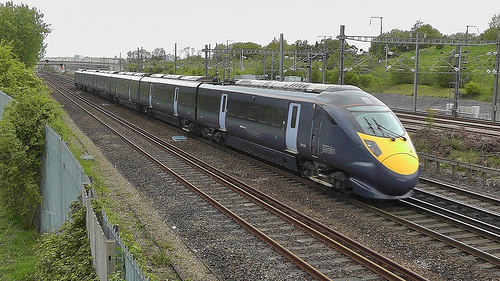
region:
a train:
[73, 30, 486, 224]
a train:
[164, 13, 422, 165]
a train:
[99, 47, 321, 192]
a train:
[178, 32, 411, 277]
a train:
[211, 68, 318, 219]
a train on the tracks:
[69, 67, 417, 207]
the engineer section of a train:
[321, 93, 421, 205]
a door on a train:
[284, 102, 303, 152]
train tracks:
[43, 78, 367, 279]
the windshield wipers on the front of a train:
[361, 116, 406, 143]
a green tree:
[1, 0, 51, 72]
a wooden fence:
[0, 90, 157, 278]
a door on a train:
[218, 90, 232, 132]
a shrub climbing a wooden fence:
[3, 78, 58, 228]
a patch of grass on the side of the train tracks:
[0, 204, 62, 278]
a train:
[220, 26, 372, 218]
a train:
[250, 87, 318, 127]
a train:
[125, 105, 320, 131]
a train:
[177, 52, 347, 145]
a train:
[236, 122, 355, 234]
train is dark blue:
[87, 56, 397, 195]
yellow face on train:
[344, 121, 415, 188]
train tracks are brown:
[97, 109, 372, 275]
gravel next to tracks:
[233, 173, 430, 256]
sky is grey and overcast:
[70, 2, 215, 53]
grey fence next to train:
[25, 118, 117, 280]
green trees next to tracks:
[16, 38, 37, 227]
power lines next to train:
[330, 22, 497, 109]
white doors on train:
[272, 96, 307, 162]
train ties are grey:
[160, 136, 333, 266]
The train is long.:
[61, 64, 445, 202]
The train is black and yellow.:
[69, 61, 429, 205]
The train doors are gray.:
[200, 82, 313, 167]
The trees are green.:
[317, 41, 488, 78]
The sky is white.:
[71, 1, 279, 31]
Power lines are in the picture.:
[200, 20, 479, 73]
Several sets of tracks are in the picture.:
[191, 76, 498, 274]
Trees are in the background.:
[279, 42, 475, 79]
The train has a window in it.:
[343, 95, 420, 152]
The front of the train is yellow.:
[333, 88, 430, 195]